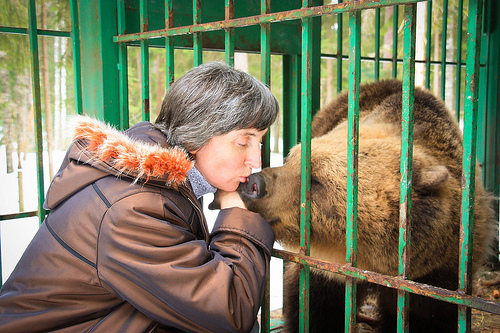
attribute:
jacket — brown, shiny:
[1, 108, 278, 330]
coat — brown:
[54, 124, 199, 331]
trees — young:
[4, 1, 83, 200]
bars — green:
[291, 170, 406, 257]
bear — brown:
[230, 76, 499, 331]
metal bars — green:
[456, 21, 472, 330]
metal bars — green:
[396, 21, 410, 329]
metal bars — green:
[346, 21, 360, 331]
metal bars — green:
[299, 22, 309, 324]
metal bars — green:
[121, 21, 129, 131]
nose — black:
[236, 174, 267, 203]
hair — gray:
[154, 50, 276, 145]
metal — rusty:
[293, 25, 486, 117]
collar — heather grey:
[183, 164, 222, 204]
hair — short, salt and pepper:
[163, 65, 275, 136]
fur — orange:
[109, 139, 177, 182]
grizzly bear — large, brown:
[232, 81, 494, 331]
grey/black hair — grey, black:
[158, 62, 279, 150]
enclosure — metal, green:
[293, 57, 493, 312]